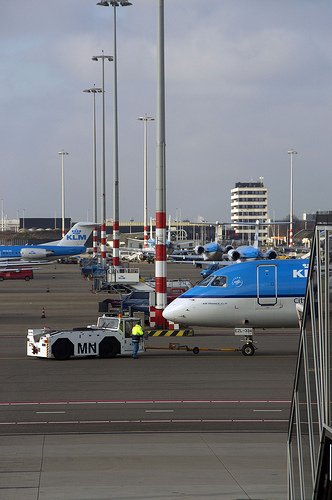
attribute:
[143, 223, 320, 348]
plane — blue, white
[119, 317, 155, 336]
coat — yellow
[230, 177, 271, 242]
tower — white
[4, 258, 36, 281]
van — red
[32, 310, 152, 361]
vehicle — white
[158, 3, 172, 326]
post — tall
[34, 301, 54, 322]
cone — orange, here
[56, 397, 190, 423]
lines — red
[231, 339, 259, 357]
tire — black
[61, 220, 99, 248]
tail — white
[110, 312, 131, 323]
light — orange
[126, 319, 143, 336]
jacket — yellow, bright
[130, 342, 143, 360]
pants — worn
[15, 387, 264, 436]
stripes — here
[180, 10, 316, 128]
sky — cloudy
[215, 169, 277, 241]
building — tall